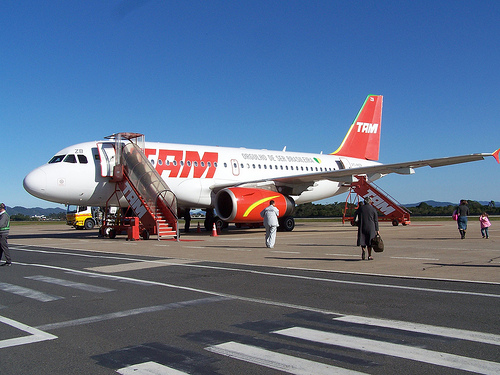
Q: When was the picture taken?
A: Daytime.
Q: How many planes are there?
A: One.